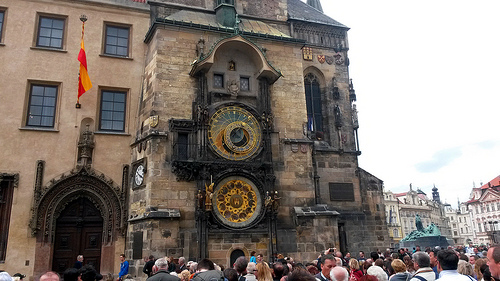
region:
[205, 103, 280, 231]
te inside of a clock on a clock tower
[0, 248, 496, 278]
a crowd of people standing outside of building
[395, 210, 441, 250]
green statue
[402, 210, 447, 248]
statue is probably made of copper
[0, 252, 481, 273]
people are looking up at tower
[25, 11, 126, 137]
four windows on building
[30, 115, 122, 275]
door with ornate design above it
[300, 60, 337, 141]
tall long skinny window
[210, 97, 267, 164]
inside of gears in top clock look like a swirl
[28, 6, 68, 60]
Small window on a building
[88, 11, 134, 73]
Small window on a building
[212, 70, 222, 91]
Small window on a building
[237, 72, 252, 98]
Small window on a building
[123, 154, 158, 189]
Clock on a building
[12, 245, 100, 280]
People stanifn on the pavement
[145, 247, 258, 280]
People standing on the pavement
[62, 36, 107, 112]
red and orange flag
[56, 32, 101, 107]
red and orange flag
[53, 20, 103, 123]
red and orange flag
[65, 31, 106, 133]
red and orange flag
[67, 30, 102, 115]
red and orange flag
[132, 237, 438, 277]
people inf ront of the church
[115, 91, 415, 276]
people inf ront of the church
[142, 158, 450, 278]
people inf ront of the church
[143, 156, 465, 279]
people inf ront of the church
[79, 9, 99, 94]
flag on the building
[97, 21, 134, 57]
window on top floor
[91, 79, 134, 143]
window on the second floor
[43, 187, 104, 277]
black door into building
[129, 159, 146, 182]
white clock on the building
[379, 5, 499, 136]
white clouds in the sky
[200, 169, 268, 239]
old design on building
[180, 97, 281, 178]
black balcony on building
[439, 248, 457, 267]
black hair on person's head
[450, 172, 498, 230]
building in the background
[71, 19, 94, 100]
a red and yellow flag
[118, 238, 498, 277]
a large crowd of people waiting outdoors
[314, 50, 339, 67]
a pair of coat of arms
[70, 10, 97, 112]
an orange and red flag hanging on the building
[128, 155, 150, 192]
a clock on the side of the building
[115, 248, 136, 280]
a man wearing blue clothes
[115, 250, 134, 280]
a man wearing blue shirt standing under the clock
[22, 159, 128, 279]
an arched doorway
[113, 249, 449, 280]
a group of people in front of the building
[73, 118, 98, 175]
a statue over the arched doorway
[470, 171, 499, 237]
a building with a red roof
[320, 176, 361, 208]
a plaque on the building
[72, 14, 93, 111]
flag hangs on building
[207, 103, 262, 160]
clock on front of building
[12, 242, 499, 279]
crowd gathers in front of building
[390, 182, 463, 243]
building is in distance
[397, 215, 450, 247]
statue is in the distance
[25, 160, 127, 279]
doorway is arched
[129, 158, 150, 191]
clock is on side of building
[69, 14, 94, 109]
flag is red and yellow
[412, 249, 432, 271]
hair is turning grey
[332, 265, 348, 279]
head is going bald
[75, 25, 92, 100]
an orange and red waving flag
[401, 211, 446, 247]
an outdoor statue in distance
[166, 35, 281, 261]
an ornate outdoor clock